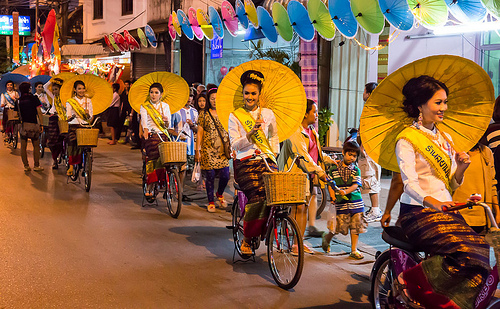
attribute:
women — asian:
[2, 55, 499, 308]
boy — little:
[323, 142, 367, 258]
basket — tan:
[257, 172, 307, 207]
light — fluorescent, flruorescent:
[432, 22, 499, 39]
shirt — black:
[14, 93, 42, 125]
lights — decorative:
[229, 19, 496, 39]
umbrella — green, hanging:
[304, 3, 338, 42]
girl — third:
[137, 83, 175, 209]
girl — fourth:
[65, 80, 96, 177]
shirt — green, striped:
[325, 157, 365, 215]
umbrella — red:
[40, 9, 58, 62]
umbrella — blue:
[258, 7, 277, 44]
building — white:
[83, 2, 174, 83]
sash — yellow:
[393, 126, 450, 188]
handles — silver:
[242, 154, 313, 172]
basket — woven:
[160, 141, 189, 168]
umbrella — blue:
[375, 1, 411, 30]